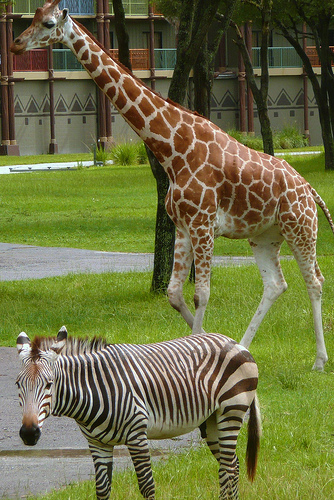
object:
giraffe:
[9, 0, 334, 379]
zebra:
[13, 324, 261, 500]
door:
[150, 29, 164, 69]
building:
[1, 0, 334, 150]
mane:
[23, 332, 108, 359]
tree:
[217, 0, 280, 158]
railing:
[104, 46, 150, 70]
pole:
[0, 0, 12, 155]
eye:
[44, 380, 54, 390]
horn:
[50, 0, 60, 10]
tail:
[306, 183, 333, 227]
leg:
[126, 434, 155, 499]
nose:
[19, 415, 38, 438]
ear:
[52, 324, 70, 358]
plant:
[80, 136, 117, 165]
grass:
[2, 126, 334, 497]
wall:
[4, 70, 330, 155]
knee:
[198, 289, 212, 315]